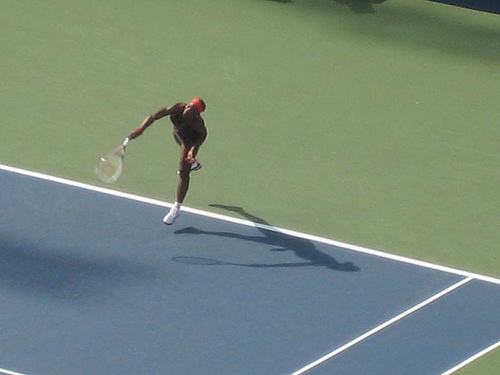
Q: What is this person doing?
A: Jumping.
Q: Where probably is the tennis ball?
A: In air.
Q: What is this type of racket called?
A: Tennis racket.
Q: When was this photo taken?
A: Daytime.